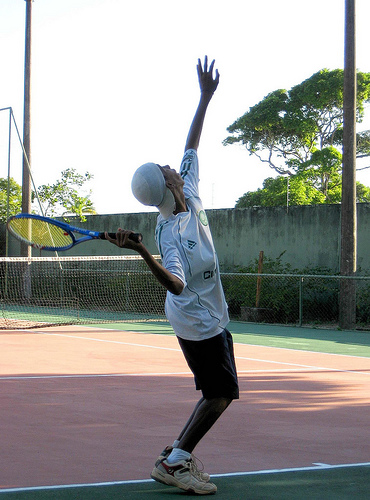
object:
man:
[103, 52, 241, 493]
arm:
[182, 96, 212, 179]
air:
[107, 26, 286, 182]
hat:
[131, 163, 176, 221]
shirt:
[155, 146, 230, 341]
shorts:
[180, 328, 240, 398]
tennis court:
[2, 320, 370, 497]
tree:
[227, 66, 370, 209]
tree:
[0, 164, 94, 222]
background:
[2, 30, 367, 269]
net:
[8, 255, 167, 331]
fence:
[2, 261, 367, 332]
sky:
[0, 0, 357, 203]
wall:
[0, 207, 367, 320]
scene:
[0, 0, 365, 499]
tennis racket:
[4, 210, 142, 249]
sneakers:
[151, 457, 218, 496]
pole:
[21, 0, 33, 303]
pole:
[338, 0, 361, 329]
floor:
[2, 313, 370, 500]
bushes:
[275, 265, 337, 325]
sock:
[167, 446, 193, 463]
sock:
[171, 437, 180, 449]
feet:
[150, 454, 218, 495]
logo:
[186, 238, 198, 250]